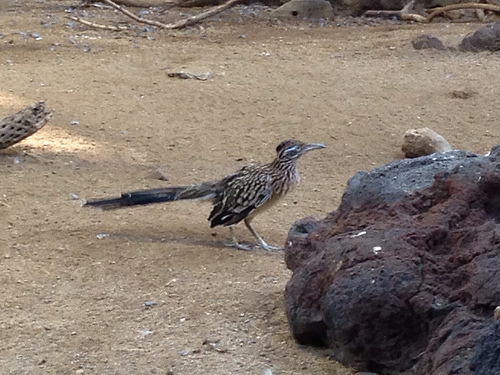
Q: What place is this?
A: It is a beach.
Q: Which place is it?
A: It is a beach.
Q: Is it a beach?
A: Yes, it is a beach.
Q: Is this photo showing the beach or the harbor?
A: It is showing the beach.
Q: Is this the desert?
A: No, it is the beach.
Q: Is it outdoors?
A: Yes, it is outdoors.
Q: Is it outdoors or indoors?
A: It is outdoors.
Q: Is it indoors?
A: No, it is outdoors.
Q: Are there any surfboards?
A: No, there are no surfboards.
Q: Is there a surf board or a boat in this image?
A: No, there are no surfboards or boats.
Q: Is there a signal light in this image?
A: No, there are no traffic lights.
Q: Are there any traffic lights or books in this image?
A: No, there are no traffic lights or books.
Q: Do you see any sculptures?
A: No, there are no sculptures.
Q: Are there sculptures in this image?
A: No, there are no sculptures.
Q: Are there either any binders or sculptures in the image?
A: No, there are no sculptures or binders.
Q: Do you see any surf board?
A: No, there are no surfboards.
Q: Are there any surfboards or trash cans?
A: No, there are no surfboards or trash cans.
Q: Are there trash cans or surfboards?
A: No, there are no surfboards or trash cans.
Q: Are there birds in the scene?
A: Yes, there is a bird.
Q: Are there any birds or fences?
A: Yes, there is a bird.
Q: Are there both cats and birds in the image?
A: No, there is a bird but no cats.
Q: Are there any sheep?
A: No, there are no sheep.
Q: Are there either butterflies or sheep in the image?
A: No, there are no sheep or butterflies.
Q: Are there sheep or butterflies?
A: No, there are no sheep or butterflies.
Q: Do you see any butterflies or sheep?
A: No, there are no sheep or butterflies.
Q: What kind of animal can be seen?
A: The animal is a bird.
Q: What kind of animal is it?
A: The animal is a bird.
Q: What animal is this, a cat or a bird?
A: That is a bird.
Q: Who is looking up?
A: The bird is looking up.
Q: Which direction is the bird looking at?
A: The bird is looking up.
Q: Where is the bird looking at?
A: The bird is looking up.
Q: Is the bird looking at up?
A: Yes, the bird is looking up.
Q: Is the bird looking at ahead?
A: No, the bird is looking up.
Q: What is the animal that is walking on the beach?
A: The animal is a bird.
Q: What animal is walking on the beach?
A: The animal is a bird.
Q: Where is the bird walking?
A: The bird is walking on the beach.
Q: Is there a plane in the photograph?
A: No, there are no airplanes.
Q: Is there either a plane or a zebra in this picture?
A: No, there are no airplanes or zebras.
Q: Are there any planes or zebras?
A: No, there are no planes or zebras.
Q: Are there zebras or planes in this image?
A: No, there are no planes or zebras.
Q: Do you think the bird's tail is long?
A: Yes, the tail is long.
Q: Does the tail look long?
A: Yes, the tail is long.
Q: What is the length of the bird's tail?
A: The tail is long.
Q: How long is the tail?
A: The tail is long.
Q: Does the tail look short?
A: No, the tail is long.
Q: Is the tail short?
A: No, the tail is long.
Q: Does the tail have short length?
A: No, the tail is long.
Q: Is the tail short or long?
A: The tail is long.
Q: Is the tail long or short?
A: The tail is long.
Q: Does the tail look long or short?
A: The tail is long.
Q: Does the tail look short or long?
A: The tail is long.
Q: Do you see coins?
A: No, there are no coins.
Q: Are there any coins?
A: No, there are no coins.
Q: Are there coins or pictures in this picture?
A: No, there are no coins or pictures.